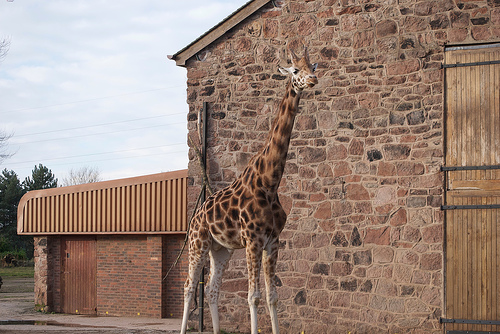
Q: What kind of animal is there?
A: Giraffe.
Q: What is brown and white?
A: The animal.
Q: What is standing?
A: The giraffe.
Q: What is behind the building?
A: Trees.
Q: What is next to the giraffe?
A: A rock building.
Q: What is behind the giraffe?
A: Building.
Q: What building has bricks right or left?
A: Left.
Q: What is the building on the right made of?
A: Stones.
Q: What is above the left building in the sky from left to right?
A: Power lines.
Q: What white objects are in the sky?
A: Clouds.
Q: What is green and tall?
A: Trees.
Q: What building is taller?
A: Right.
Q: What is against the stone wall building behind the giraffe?
A: Pole.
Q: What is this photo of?
A: A giraffe.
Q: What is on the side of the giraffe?
A: A wall.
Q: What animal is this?
A: Giraffe.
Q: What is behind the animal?
A: Stone building.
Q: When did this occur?
A: Daytime.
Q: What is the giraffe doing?
A: Standing.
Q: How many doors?
A: Two.